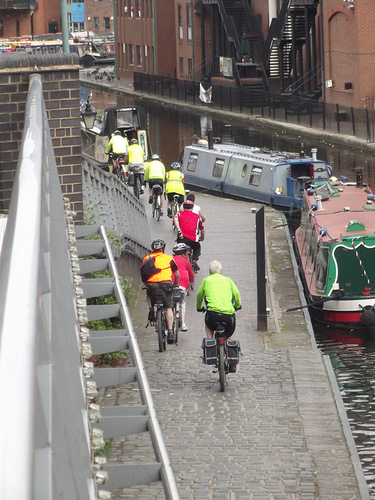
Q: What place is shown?
A: It is a sidewalk.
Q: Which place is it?
A: It is a sidewalk.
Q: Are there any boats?
A: Yes, there is a boat.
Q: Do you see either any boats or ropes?
A: Yes, there is a boat.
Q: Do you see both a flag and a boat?
A: No, there is a boat but no flags.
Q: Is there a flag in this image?
A: No, there are no flags.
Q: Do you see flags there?
A: No, there are no flags.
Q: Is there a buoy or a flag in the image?
A: No, there are no flags or buoys.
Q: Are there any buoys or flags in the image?
A: No, there are no flags or buoys.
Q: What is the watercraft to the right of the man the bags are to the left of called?
A: The watercraft is a boat.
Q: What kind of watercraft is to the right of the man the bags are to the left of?
A: The watercraft is a boat.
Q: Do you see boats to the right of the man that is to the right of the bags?
A: Yes, there is a boat to the right of the man.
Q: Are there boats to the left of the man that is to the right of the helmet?
A: No, the boat is to the right of the man.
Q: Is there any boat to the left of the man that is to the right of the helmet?
A: No, the boat is to the right of the man.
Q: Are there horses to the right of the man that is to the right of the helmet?
A: No, there is a boat to the right of the man.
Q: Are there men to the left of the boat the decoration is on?
A: Yes, there is a man to the left of the boat.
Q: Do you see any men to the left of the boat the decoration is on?
A: Yes, there is a man to the left of the boat.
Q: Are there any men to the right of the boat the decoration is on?
A: No, the man is to the left of the boat.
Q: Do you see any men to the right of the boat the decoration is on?
A: No, the man is to the left of the boat.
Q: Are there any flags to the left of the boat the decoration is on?
A: No, there is a man to the left of the boat.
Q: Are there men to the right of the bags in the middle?
A: Yes, there is a man to the right of the bags.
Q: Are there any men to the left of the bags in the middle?
A: No, the man is to the right of the bags.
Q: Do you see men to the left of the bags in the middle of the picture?
A: No, the man is to the right of the bags.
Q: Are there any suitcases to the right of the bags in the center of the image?
A: No, there is a man to the right of the bags.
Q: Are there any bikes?
A: Yes, there is a bike.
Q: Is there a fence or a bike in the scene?
A: Yes, there is a bike.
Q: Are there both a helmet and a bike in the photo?
A: Yes, there are both a bike and a helmet.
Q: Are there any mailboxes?
A: No, there are no mailboxes.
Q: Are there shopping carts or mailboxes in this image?
A: No, there are no mailboxes or shopping carts.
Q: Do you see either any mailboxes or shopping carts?
A: No, there are no mailboxes or shopping carts.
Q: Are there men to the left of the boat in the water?
A: Yes, there is a man to the left of the boat.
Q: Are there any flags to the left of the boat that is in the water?
A: No, there is a man to the left of the boat.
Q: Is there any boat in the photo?
A: Yes, there is a boat.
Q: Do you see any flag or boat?
A: Yes, there is a boat.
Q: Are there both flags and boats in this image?
A: No, there is a boat but no flags.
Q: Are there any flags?
A: No, there are no flags.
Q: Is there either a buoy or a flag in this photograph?
A: No, there are no flags or buoys.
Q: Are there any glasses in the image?
A: No, there are no glasses.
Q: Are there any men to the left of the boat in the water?
A: Yes, there is a man to the left of the boat.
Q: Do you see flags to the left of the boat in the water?
A: No, there is a man to the left of the boat.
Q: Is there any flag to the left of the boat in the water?
A: No, there is a man to the left of the boat.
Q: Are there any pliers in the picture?
A: No, there are no pliers.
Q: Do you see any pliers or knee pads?
A: No, there are no pliers or knee pads.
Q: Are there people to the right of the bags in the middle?
A: Yes, there is a person to the right of the bags.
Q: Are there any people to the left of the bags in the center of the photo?
A: No, the person is to the right of the bags.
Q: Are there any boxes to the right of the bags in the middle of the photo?
A: No, there is a person to the right of the bags.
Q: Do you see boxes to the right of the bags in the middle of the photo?
A: No, there is a person to the right of the bags.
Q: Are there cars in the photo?
A: No, there are no cars.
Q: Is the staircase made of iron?
A: Yes, the staircase is made of iron.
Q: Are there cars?
A: No, there are no cars.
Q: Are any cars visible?
A: No, there are no cars.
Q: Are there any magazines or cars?
A: No, there are no cars or magazines.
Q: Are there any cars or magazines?
A: No, there are no cars or magazines.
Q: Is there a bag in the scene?
A: Yes, there is a bag.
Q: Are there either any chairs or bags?
A: Yes, there is a bag.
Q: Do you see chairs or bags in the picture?
A: Yes, there is a bag.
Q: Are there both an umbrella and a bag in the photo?
A: No, there is a bag but no umbrellas.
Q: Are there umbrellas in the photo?
A: No, there are no umbrellas.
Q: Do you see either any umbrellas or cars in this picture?
A: No, there are no umbrellas or cars.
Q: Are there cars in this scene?
A: No, there are no cars.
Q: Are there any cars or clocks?
A: No, there are no cars or clocks.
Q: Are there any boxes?
A: No, there are no boxes.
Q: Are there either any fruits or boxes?
A: No, there are no boxes or fruits.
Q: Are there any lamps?
A: No, there are no lamps.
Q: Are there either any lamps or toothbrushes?
A: No, there are no lamps or toothbrushes.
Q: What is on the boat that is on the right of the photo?
A: The decoration is on the boat.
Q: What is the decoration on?
A: The decoration is on the boat.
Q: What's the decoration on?
A: The decoration is on the boat.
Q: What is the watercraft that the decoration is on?
A: The watercraft is a boat.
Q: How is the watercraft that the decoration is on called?
A: The watercraft is a boat.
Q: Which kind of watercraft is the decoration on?
A: The decoration is on the boat.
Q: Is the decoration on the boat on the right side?
A: Yes, the decoration is on the boat.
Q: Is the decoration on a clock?
A: No, the decoration is on the boat.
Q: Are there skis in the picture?
A: No, there are no skis.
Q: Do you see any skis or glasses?
A: No, there are no skis or glasses.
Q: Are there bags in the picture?
A: Yes, there is a bag.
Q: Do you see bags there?
A: Yes, there is a bag.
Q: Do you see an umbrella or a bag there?
A: Yes, there is a bag.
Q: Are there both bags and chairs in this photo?
A: No, there is a bag but no chairs.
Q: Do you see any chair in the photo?
A: No, there are no chairs.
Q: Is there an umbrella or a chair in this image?
A: No, there are no chairs or umbrellas.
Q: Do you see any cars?
A: No, there are no cars.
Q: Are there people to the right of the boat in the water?
A: No, the person is to the left of the boat.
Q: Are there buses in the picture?
A: No, there are no buses.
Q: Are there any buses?
A: No, there are no buses.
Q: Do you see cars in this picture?
A: No, there are no cars.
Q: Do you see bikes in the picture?
A: Yes, there is a bike.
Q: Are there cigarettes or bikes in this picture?
A: Yes, there is a bike.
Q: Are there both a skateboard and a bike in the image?
A: No, there is a bike but no skateboards.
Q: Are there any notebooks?
A: No, there are no notebooks.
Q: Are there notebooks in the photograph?
A: No, there are no notebooks.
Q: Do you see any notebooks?
A: No, there are no notebooks.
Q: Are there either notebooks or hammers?
A: No, there are no notebooks or hammers.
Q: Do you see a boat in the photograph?
A: Yes, there is a boat.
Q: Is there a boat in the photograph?
A: Yes, there is a boat.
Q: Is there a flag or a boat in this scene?
A: Yes, there is a boat.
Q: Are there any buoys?
A: No, there are no buoys.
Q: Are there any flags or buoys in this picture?
A: No, there are no buoys or flags.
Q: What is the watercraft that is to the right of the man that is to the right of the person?
A: The watercraft is a boat.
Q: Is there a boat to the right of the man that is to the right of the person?
A: Yes, there is a boat to the right of the man.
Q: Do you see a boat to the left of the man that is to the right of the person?
A: No, the boat is to the right of the man.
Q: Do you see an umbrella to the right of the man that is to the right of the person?
A: No, there is a boat to the right of the man.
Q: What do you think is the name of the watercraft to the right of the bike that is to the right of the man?
A: The watercraft is a boat.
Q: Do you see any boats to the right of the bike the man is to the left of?
A: Yes, there is a boat to the right of the bike.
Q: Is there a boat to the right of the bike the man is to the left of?
A: Yes, there is a boat to the right of the bike.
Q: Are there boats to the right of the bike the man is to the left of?
A: Yes, there is a boat to the right of the bike.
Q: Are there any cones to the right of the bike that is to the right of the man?
A: No, there is a boat to the right of the bike.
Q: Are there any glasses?
A: No, there are no glasses.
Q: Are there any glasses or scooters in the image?
A: No, there are no glasses or scooters.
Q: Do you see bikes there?
A: Yes, there is a bike.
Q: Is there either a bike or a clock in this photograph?
A: Yes, there is a bike.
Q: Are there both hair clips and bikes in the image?
A: No, there is a bike but no hair clips.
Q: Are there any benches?
A: No, there are no benches.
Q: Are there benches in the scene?
A: No, there are no benches.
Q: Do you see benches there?
A: No, there are no benches.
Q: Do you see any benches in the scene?
A: No, there are no benches.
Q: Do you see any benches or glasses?
A: No, there are no benches or glasses.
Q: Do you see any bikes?
A: Yes, there is a bike.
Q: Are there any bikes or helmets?
A: Yes, there is a bike.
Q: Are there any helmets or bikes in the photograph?
A: Yes, there is a bike.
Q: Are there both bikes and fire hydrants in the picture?
A: No, there is a bike but no fire hydrants.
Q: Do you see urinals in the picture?
A: No, there are no urinals.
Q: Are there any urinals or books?
A: No, there are no urinals or books.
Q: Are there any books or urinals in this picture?
A: No, there are no urinals or books.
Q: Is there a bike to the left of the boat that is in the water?
A: Yes, there is a bike to the left of the boat.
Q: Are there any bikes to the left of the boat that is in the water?
A: Yes, there is a bike to the left of the boat.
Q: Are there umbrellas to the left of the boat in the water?
A: No, there is a bike to the left of the boat.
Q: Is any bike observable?
A: Yes, there is a bike.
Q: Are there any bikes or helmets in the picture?
A: Yes, there is a bike.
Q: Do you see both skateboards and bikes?
A: No, there is a bike but no skateboards.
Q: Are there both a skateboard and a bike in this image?
A: No, there is a bike but no skateboards.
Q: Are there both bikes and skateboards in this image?
A: No, there is a bike but no skateboards.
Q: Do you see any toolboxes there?
A: No, there are no toolboxes.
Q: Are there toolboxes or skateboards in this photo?
A: No, there are no toolboxes or skateboards.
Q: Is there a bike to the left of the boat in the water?
A: Yes, there is a bike to the left of the boat.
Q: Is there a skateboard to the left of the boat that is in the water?
A: No, there is a bike to the left of the boat.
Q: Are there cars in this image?
A: No, there are no cars.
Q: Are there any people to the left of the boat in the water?
A: Yes, there is a person to the left of the boat.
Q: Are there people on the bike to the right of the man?
A: Yes, there is a person on the bike.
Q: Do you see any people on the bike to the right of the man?
A: Yes, there is a person on the bike.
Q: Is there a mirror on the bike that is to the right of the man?
A: No, there is a person on the bike.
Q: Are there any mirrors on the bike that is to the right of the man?
A: No, there is a person on the bike.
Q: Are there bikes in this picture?
A: Yes, there is a bike.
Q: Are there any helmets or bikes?
A: Yes, there is a bike.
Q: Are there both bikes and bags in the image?
A: Yes, there are both a bike and a bag.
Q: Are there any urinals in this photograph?
A: No, there are no urinals.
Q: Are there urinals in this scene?
A: No, there are no urinals.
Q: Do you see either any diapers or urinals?
A: No, there are no urinals or diapers.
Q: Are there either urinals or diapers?
A: No, there are no urinals or diapers.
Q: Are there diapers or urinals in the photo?
A: No, there are no urinals or diapers.